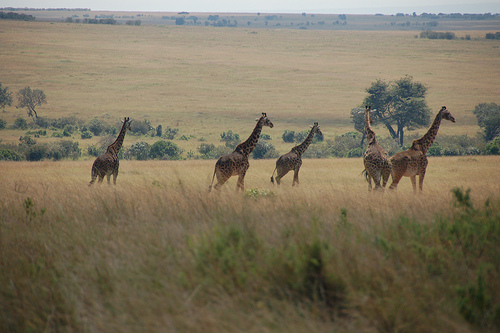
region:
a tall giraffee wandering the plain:
[87, 114, 126, 181]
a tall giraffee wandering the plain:
[204, 110, 272, 195]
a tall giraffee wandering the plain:
[274, 121, 321, 181]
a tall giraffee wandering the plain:
[357, 103, 392, 189]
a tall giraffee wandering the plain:
[390, 106, 452, 187]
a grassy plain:
[2, 19, 498, 331]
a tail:
[205, 162, 220, 189]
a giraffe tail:
[268, 161, 280, 183]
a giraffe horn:
[258, 111, 263, 116]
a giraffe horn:
[262, 111, 268, 120]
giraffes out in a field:
[61, 91, 483, 221]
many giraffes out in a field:
[17, 68, 469, 225]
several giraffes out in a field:
[72, 71, 472, 230]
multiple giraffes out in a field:
[41, 58, 478, 213]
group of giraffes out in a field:
[23, 62, 466, 227]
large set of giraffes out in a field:
[44, 51, 466, 225]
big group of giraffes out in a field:
[58, 47, 466, 229]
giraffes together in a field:
[58, 34, 463, 249]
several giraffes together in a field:
[34, 38, 472, 230]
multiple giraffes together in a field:
[57, 63, 461, 220]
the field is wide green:
[59, 20, 380, 135]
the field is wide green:
[190, 50, 384, 184]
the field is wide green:
[155, 30, 336, 90]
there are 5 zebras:
[29, 85, 449, 183]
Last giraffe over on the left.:
[85, 113, 133, 188]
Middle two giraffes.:
[203, 110, 323, 191]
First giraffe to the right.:
[381, 104, 456, 195]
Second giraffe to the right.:
[360, 101, 392, 190]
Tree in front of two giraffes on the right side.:
[359, 74, 432, 155]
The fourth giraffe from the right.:
[210, 109, 272, 192]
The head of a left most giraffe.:
[117, 113, 136, 132]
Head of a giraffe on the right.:
[437, 105, 457, 125]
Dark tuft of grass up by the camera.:
[290, 236, 348, 316]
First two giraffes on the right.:
[358, 99, 454, 194]